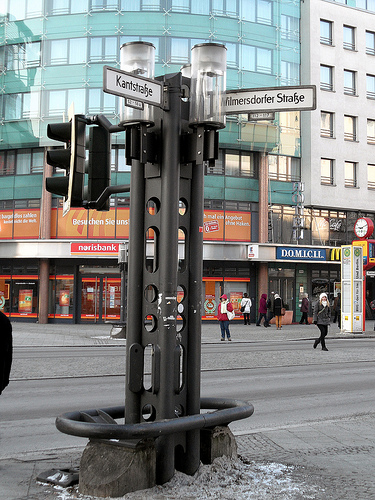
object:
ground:
[318, 93, 342, 118]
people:
[240, 291, 252, 326]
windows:
[226, 153, 253, 177]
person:
[216, 291, 234, 341]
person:
[313, 292, 330, 351]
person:
[0, 298, 13, 396]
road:
[0, 320, 375, 499]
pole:
[125, 137, 143, 427]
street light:
[119, 41, 154, 78]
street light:
[117, 96, 153, 126]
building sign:
[281, 248, 325, 259]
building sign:
[79, 243, 117, 253]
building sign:
[73, 218, 129, 226]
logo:
[330, 248, 341, 260]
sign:
[218, 86, 315, 114]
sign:
[103, 65, 164, 107]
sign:
[339, 244, 363, 330]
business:
[271, 243, 375, 327]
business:
[0, 202, 254, 323]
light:
[45, 114, 76, 217]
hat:
[319, 292, 327, 300]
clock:
[354, 217, 374, 239]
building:
[1, 1, 374, 321]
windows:
[1, 37, 41, 74]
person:
[299, 291, 310, 323]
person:
[255, 292, 269, 326]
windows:
[76, 271, 122, 325]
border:
[0, 309, 254, 320]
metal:
[162, 165, 177, 193]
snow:
[212, 463, 243, 480]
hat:
[219, 294, 227, 300]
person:
[273, 293, 284, 329]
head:
[319, 292, 328, 303]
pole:
[154, 70, 183, 487]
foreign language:
[116, 75, 155, 98]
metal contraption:
[39, 37, 316, 479]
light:
[186, 37, 228, 124]